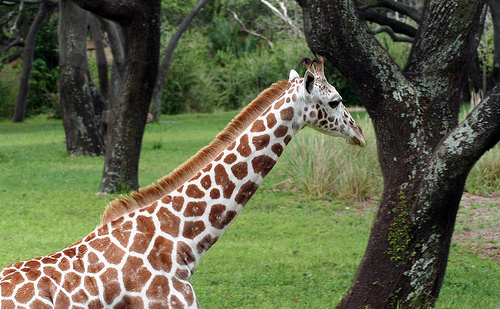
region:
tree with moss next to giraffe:
[307, 5, 498, 307]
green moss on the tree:
[366, 33, 486, 305]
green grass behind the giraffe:
[5, 113, 493, 307]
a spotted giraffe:
[5, 62, 363, 305]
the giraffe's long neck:
[158, 94, 294, 269]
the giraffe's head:
[287, 55, 364, 146]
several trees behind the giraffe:
[18, 11, 185, 208]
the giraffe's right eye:
[325, 100, 338, 108]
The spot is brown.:
[14, 277, 39, 307]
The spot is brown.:
[61, 270, 84, 296]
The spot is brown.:
[84, 248, 107, 275]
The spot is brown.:
[120, 252, 152, 294]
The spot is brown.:
[143, 228, 175, 278]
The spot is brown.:
[88, 233, 110, 253]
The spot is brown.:
[153, 204, 180, 237]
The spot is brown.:
[182, 218, 205, 241]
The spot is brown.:
[181, 196, 208, 219]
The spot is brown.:
[183, 180, 205, 200]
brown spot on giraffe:
[278, 106, 294, 122]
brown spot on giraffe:
[250, 132, 272, 149]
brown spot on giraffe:
[250, 153, 275, 178]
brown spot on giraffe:
[213, 163, 234, 199]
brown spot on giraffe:
[183, 180, 203, 200]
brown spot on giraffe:
[181, 200, 208, 216]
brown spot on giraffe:
[180, 218, 202, 239]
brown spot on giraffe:
[155, 205, 180, 237]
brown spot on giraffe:
[170, 275, 192, 304]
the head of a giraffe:
[304, 83, 353, 119]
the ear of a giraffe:
[283, 45, 336, 100]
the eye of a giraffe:
[317, 90, 347, 120]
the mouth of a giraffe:
[332, 105, 396, 170]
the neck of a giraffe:
[113, 107, 302, 295]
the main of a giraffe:
[74, 50, 302, 246]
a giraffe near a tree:
[81, 36, 470, 282]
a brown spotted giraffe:
[127, 51, 334, 269]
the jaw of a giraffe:
[292, 108, 345, 133]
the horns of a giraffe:
[268, 36, 383, 96]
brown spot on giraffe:
[271, 97, 288, 109]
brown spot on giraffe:
[249, 115, 266, 132]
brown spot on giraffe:
[199, 175, 211, 189]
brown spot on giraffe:
[207, 185, 220, 198]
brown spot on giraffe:
[102, 240, 126, 264]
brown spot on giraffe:
[69, 258, 87, 272]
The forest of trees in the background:
[5, 6, 494, 119]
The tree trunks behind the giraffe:
[32, 0, 207, 203]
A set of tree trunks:
[31, 2, 171, 192]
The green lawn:
[3, 105, 472, 306]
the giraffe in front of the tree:
[1, 55, 361, 305]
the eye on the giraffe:
[328, 95, 338, 107]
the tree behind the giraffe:
[66, 0, 161, 190]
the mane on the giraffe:
[98, 77, 288, 225]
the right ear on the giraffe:
[303, 68, 313, 89]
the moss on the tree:
[387, 192, 412, 264]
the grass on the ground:
[1, 118, 491, 299]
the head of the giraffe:
[296, 56, 364, 142]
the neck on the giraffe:
[175, 112, 303, 267]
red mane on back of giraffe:
[97, 54, 369, 264]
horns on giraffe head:
[290, 52, 370, 149]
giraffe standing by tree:
[97, 42, 464, 302]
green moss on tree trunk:
[382, 183, 428, 278]